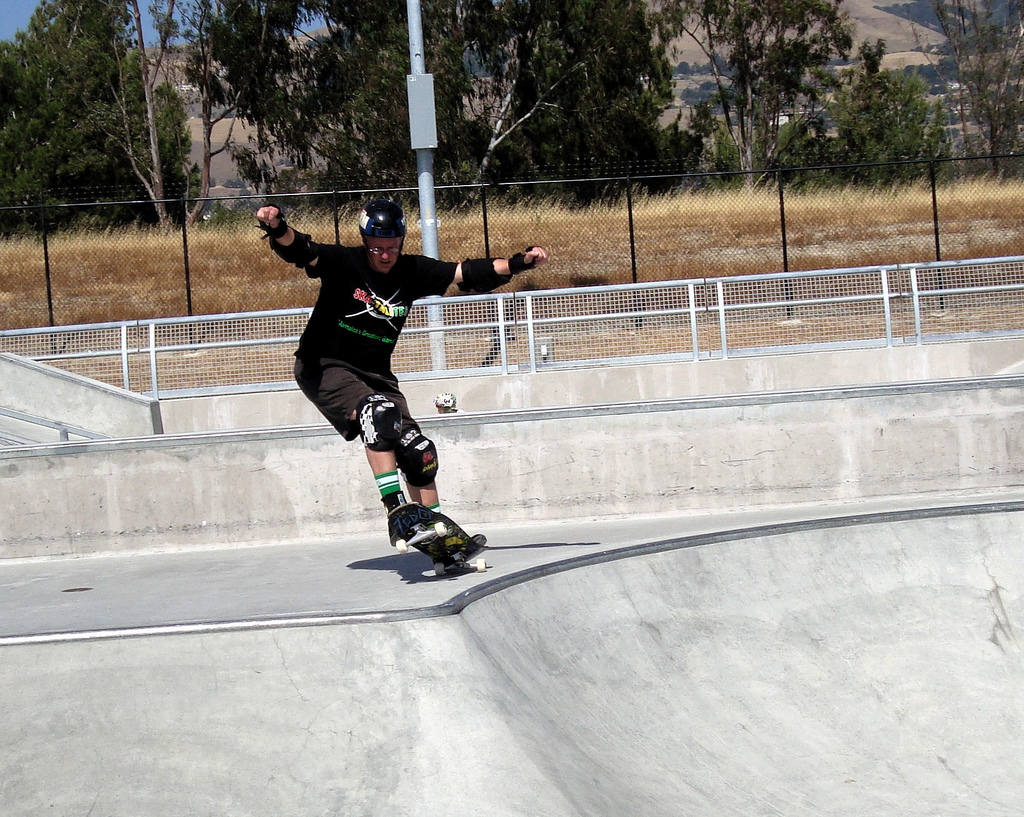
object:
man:
[250, 197, 555, 520]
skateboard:
[385, 499, 489, 575]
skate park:
[0, 257, 1024, 817]